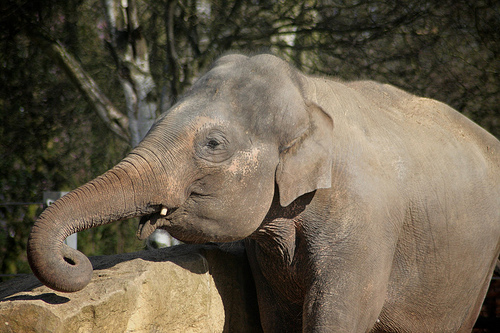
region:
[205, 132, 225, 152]
an elephant's left eye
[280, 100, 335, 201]
an elephant's ear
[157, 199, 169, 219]
a white ivory tusk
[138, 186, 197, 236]
the mouth of an elephant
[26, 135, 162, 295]
the trunk of an elephant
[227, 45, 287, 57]
hair on an elephants head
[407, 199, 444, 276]
the wrinkled skin of an elephant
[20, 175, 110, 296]
an elephant's curled trunk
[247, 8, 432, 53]
branches on a tree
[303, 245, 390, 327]
the front left leg of an elephant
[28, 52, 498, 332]
the elephant is gray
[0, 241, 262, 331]
stone wall behind elephant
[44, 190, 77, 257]
grey pole behind wall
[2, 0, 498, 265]
trees stand high behind wall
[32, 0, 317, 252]
tree has white bark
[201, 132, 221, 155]
elephant has black eyes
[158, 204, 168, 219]
white tusk on elephant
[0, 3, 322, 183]
building hidden behind tree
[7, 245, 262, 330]
elephant is casting shadow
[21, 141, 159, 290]
elephant trunk is curled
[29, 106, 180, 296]
the trunk of the elephant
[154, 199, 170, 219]
the thooth of the elephant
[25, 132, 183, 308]
wrinkles on the trunk of the elephant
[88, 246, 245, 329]
the stone wall by the elephant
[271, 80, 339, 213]
the ear of the elephant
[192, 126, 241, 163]
the wrinkles around the eye of the elephant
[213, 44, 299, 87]
hair on the mups on the elephant head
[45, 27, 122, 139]
the moss on the branch of the tree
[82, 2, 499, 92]
the tree behind the wall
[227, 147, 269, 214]
the white marks on the face of the elephant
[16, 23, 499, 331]
gray elephant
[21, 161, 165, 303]
bottom of trunk is curled under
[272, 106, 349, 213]
small gray ear on the side of the head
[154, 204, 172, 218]
small white tusk on the side of the trunk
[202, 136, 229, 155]
small black eye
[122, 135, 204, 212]
spots on the skin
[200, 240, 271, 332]
shadow from the elephant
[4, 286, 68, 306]
shadow on the rock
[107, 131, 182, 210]
lines on the trunk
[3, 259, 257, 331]
large rock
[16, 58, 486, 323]
elephant near a rock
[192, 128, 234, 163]
eye on the elephant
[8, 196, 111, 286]
trunk of the elephant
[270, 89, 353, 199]
ear of the elephant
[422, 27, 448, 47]
leaves of the tree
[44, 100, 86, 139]
leaves of the tree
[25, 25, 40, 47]
leaves of the tree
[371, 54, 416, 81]
leaves of the tree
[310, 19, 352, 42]
leaves of the tree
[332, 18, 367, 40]
leaves of the tree